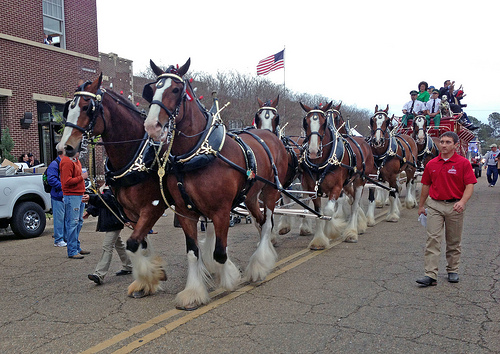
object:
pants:
[425, 198, 463, 277]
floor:
[0, 161, 499, 354]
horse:
[142, 57, 290, 311]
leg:
[174, 251, 215, 311]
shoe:
[415, 276, 437, 286]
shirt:
[421, 152, 478, 201]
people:
[401, 80, 480, 132]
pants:
[63, 195, 85, 258]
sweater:
[59, 156, 85, 196]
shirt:
[46, 156, 63, 201]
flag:
[257, 49, 284, 77]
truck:
[0, 175, 52, 238]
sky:
[96, 0, 500, 129]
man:
[414, 130, 477, 288]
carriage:
[398, 113, 462, 139]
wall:
[0, 0, 109, 186]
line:
[77, 200, 422, 353]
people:
[43, 149, 91, 259]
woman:
[417, 81, 430, 102]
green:
[416, 91, 430, 102]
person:
[44, 32, 53, 44]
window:
[42, 0, 67, 50]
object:
[20, 112, 33, 129]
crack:
[474, 250, 500, 354]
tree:
[139, 66, 372, 139]